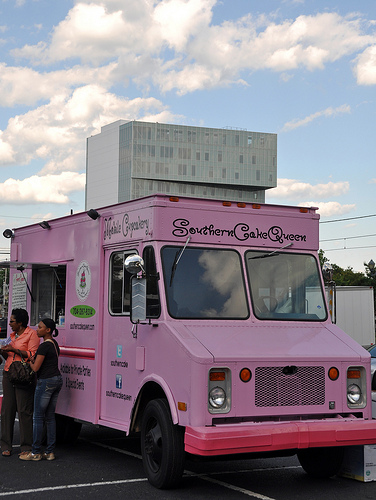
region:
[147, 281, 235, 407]
the truck is pink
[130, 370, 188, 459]
the truck is pink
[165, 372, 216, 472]
the truck is pink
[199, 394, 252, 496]
the truck is pink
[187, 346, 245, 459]
the truck is pink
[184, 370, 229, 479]
the truck is pink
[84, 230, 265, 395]
the truck is pink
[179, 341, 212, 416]
the truck is pink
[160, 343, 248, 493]
the truck is pink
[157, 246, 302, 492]
the truck is pink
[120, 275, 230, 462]
the truck is pink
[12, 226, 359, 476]
The truck is pink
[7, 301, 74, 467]
People are standing by the truck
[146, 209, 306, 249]
The writing is black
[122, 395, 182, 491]
The wheels and rims are black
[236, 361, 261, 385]
Round orange light on the front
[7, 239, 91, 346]
The truck window is open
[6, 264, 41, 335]
White and black sign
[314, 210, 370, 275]
Multiple black power lines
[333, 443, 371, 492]
Box under the truck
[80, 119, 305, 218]
A tall white building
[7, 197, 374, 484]
the pink cake truck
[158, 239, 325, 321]
the windshield to the pink truck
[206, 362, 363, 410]
the headlights on the truck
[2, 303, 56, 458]
the people on the side of the truck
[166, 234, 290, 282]
the black windshield wipers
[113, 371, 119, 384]
the facebook logo on the truck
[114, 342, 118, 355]
the twitter logo on the truck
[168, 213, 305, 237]
the name of the company on the front of the truck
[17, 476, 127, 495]
the white lines on the ground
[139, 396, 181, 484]
the front wheel on the truck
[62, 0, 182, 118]
clouds in the sky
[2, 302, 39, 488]
woman in pink shirt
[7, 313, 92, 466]
women in black shirt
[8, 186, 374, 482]
pink van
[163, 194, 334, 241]
writing on pink van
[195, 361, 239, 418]
an orange and white headlight.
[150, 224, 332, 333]
front windows of van.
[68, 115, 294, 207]
grey building with lots of windows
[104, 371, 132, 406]
Facebook link symbol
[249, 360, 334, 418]
pink van's frontal grill